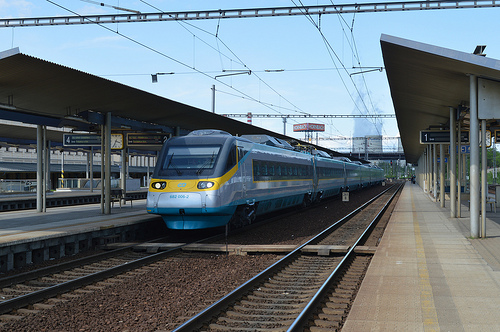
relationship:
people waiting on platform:
[404, 169, 420, 186] [337, 169, 498, 322]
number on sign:
[161, 133, 170, 143] [119, 129, 179, 152]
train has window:
[145, 128, 385, 230] [162, 145, 221, 170]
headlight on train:
[196, 179, 215, 189] [165, 119, 445, 241]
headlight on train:
[151, 181, 169, 191] [165, 119, 445, 241]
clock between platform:
[107, 130, 128, 150] [366, 183, 477, 330]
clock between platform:
[107, 130, 128, 150] [1, 203, 156, 241]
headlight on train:
[149, 181, 168, 189] [145, 128, 385, 230]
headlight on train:
[196, 179, 214, 191] [145, 128, 385, 230]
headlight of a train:
[149, 181, 168, 189] [145, 128, 385, 230]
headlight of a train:
[196, 179, 214, 191] [145, 128, 385, 230]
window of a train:
[159, 142, 219, 172] [145, 128, 385, 230]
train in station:
[141, 128, 386, 234] [44, 42, 467, 298]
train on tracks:
[145, 128, 385, 230] [0, 180, 407, 329]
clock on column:
[107, 130, 128, 150] [99, 120, 113, 224]